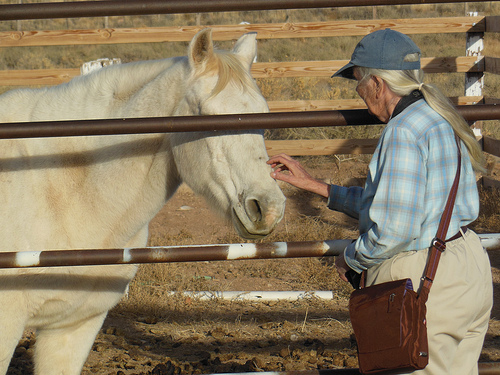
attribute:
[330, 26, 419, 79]
baseball cap — grey, blue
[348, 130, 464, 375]
messenger bag — small, brown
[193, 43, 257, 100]
hair — blond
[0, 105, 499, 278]
fence — brown, metal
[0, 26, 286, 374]
horse — white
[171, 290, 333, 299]
pole — white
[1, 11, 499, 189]
fence — wooden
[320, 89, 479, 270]
shirt — blue plaid, blue white, tan, blue, long sleeved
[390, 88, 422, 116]
collar — black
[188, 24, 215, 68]
ear — pointy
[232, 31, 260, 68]
ear — pointy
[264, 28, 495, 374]
woman — older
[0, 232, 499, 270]
bar — rusty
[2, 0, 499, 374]
field — rocky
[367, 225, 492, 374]
pants — long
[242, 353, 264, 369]
mud clump — small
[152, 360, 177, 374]
mud clump — small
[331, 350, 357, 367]
mud clump — small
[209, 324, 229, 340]
mud clump — small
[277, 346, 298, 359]
mud clump — small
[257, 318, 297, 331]
mud clump — small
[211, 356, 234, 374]
mud clump — small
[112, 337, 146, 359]
mud clump — small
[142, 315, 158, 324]
mud clump — small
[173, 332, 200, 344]
mud clump — small